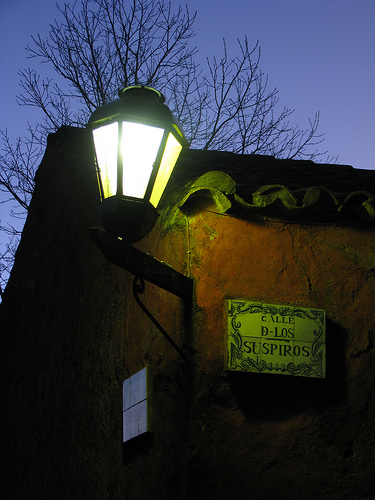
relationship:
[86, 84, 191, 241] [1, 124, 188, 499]
light near wall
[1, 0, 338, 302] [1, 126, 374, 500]
tree behind building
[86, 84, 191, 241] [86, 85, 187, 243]
light has frame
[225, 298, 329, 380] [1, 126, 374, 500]
sign on building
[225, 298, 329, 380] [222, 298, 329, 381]
sign made of tile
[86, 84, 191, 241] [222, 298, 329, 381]
light shining on tile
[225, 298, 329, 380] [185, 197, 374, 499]
sign on wall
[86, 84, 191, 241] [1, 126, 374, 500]
light on building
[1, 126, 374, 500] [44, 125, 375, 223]
building has shingles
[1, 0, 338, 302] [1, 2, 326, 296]
tree has branches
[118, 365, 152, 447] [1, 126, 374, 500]
window on building